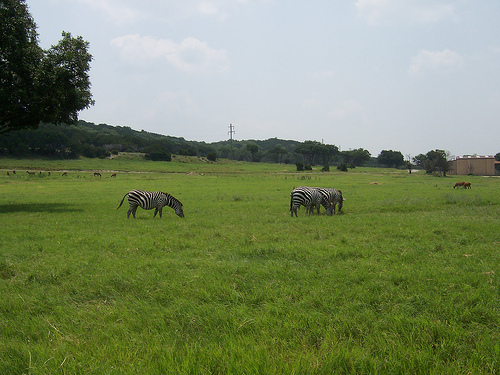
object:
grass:
[391, 340, 500, 375]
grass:
[193, 165, 237, 204]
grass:
[411, 356, 500, 375]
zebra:
[289, 186, 334, 218]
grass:
[80, 155, 126, 168]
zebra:
[321, 188, 346, 216]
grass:
[0, 300, 74, 375]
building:
[448, 154, 496, 175]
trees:
[418, 149, 451, 178]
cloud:
[105, 28, 144, 49]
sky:
[171, 5, 205, 38]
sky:
[418, 10, 482, 80]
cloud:
[403, 40, 463, 82]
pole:
[230, 123, 233, 139]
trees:
[201, 137, 291, 165]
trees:
[93, 123, 133, 158]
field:
[0, 168, 500, 375]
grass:
[373, 191, 467, 212]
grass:
[113, 320, 213, 370]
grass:
[2, 157, 38, 166]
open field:
[0, 159, 500, 374]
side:
[446, 37, 497, 272]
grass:
[278, 208, 316, 230]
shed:
[447, 153, 496, 175]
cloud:
[249, 119, 283, 132]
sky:
[268, 100, 332, 129]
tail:
[116, 192, 129, 210]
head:
[175, 207, 185, 218]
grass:
[12, 210, 63, 240]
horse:
[94, 172, 102, 176]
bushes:
[123, 125, 324, 159]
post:
[228, 123, 236, 139]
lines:
[227, 125, 229, 135]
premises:
[446, 154, 494, 175]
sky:
[98, 18, 131, 46]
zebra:
[117, 189, 185, 219]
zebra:
[305, 188, 346, 216]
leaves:
[60, 91, 83, 102]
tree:
[0, 8, 94, 159]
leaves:
[15, 64, 35, 74]